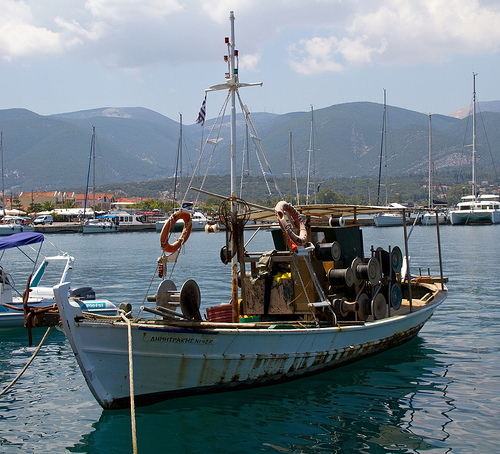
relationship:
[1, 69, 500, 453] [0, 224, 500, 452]
boats floating on water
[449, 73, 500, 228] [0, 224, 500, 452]
boat in water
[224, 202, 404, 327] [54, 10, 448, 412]
equipment on top of boat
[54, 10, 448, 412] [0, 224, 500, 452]
boat on top of water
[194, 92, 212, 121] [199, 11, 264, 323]
flag on post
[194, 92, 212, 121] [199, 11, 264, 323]
flag on a post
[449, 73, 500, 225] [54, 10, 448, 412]
boat behind boat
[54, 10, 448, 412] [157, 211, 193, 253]
boat with lifesaver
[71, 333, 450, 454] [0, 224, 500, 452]
reflection in water